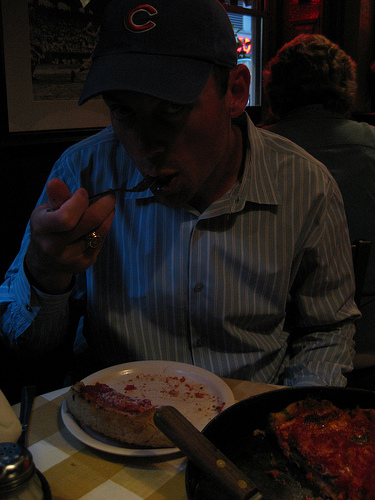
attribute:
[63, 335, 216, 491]
pizza — half-eaten, chicago-style, deep-dish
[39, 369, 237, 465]
plate — half-full, white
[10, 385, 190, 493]
table — checked, yellow, white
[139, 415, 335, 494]
knife — brown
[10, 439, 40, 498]
dispenser — cheese, parmesan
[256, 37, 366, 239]
woman — in background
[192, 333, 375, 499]
platter — black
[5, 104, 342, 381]
shirt — blue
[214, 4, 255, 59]
sign — neon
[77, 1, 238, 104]
hat — blue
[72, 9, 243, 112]
cap — baseball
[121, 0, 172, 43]
logo — Chicago cubs